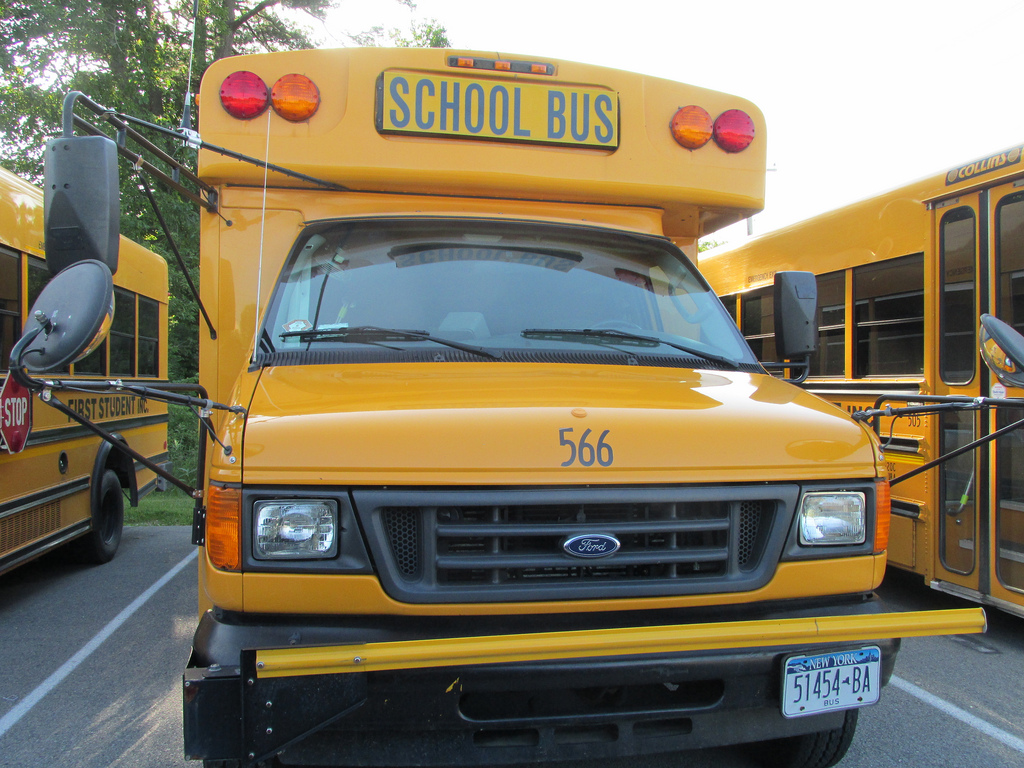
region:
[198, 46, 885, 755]
Front of the school bus.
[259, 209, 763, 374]
Windshield of the bus.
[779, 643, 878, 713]
School bus license plate.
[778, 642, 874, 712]
New York license plate on the front.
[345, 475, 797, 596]
The front end bus spoiler.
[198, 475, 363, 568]
Right side head lights.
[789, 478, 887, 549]
Left side head lights.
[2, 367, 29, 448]
School bus stop sign on the side of it.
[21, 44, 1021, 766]
Large yellow school bus is parked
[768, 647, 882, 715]
License plates attached to the bus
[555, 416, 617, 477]
number 566 decal printed onto the bus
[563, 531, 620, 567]
FORD metal logo on the bus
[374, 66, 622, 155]
SCHOOL BUS sign on the bus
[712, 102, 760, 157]
Circular red light next to an orange circular light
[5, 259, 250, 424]
Large circular light on the bus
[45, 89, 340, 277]
Large black rectangular light on the bus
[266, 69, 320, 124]
Circular orange light next to the red light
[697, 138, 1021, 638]
Yellow bus parked next to a yellow bus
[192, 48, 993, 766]
yellow school pus parked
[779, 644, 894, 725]
license plate on front of bus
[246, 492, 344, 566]
clear headlight on bus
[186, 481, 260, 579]
orange light on bus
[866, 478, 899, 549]
orange light on bus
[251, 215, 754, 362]
windshield on front of bus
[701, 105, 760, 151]
red light on bus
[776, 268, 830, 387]
mirror on side of bus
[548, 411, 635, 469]
number of the school bus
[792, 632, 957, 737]
license plate on the school bus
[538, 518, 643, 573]
ford symbol on the bus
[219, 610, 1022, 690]
crossing arm on the bus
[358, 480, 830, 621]
grill of the school bus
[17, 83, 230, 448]
mirror with round and rectangle together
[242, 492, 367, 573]
A light on a vehicle.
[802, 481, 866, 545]
A light on a vehicle.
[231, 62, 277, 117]
A light on a vehicle.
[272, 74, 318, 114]
A light on a vehicle.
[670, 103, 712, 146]
A light on a vehicle.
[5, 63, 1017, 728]
Three school buses in a lot.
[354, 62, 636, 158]
School Bus is written on the bus.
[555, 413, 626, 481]
The bus is number 566.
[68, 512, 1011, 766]
The bus is parked in a parking spot marked with white lines.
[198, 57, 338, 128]
Orange and red lights on the bus.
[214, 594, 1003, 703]
A yellow metal post at an angle on the front of the bus.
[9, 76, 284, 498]
Large mirrors on the side of the bus.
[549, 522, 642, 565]
A Ford emblem on the grill.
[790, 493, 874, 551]
Headlight of a yellow school bus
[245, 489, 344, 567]
Headlight of a school bus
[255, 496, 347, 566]
Headlight of a yellow school bus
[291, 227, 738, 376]
Window of a school bus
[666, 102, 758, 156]
Lights on a yellow school bus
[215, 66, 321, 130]
Lights on a school bus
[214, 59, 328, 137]
Lights on a yellow school bus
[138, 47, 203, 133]
green leaves on the tree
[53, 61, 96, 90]
green leaves on the tree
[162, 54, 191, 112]
green leaves on the tree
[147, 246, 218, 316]
green leaves on the tree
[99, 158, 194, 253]
green leaves on the tree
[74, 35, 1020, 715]
this is a school bus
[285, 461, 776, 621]
the bumper is metal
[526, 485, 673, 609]
the logo is round